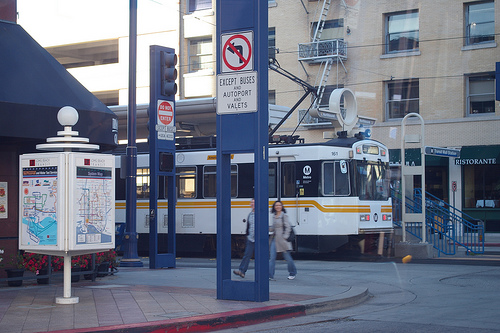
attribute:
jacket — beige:
[270, 211, 294, 252]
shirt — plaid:
[247, 210, 256, 242]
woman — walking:
[269, 201, 297, 282]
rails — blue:
[392, 186, 486, 256]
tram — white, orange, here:
[108, 137, 393, 260]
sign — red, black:
[219, 30, 255, 74]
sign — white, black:
[217, 72, 259, 114]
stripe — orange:
[116, 198, 393, 213]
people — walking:
[234, 199, 297, 280]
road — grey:
[113, 254, 500, 331]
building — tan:
[17, 1, 499, 248]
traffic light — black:
[160, 52, 178, 98]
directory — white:
[18, 105, 116, 306]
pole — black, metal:
[127, 0, 137, 148]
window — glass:
[381, 77, 422, 122]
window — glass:
[462, 70, 499, 118]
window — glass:
[462, 0, 499, 51]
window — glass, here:
[184, 34, 215, 75]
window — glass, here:
[183, 0, 214, 18]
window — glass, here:
[267, 25, 276, 70]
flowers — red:
[20, 251, 117, 272]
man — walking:
[233, 198, 256, 279]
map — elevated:
[18, 153, 63, 250]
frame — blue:
[215, 0, 270, 303]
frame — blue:
[149, 45, 176, 270]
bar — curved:
[401, 112, 428, 244]